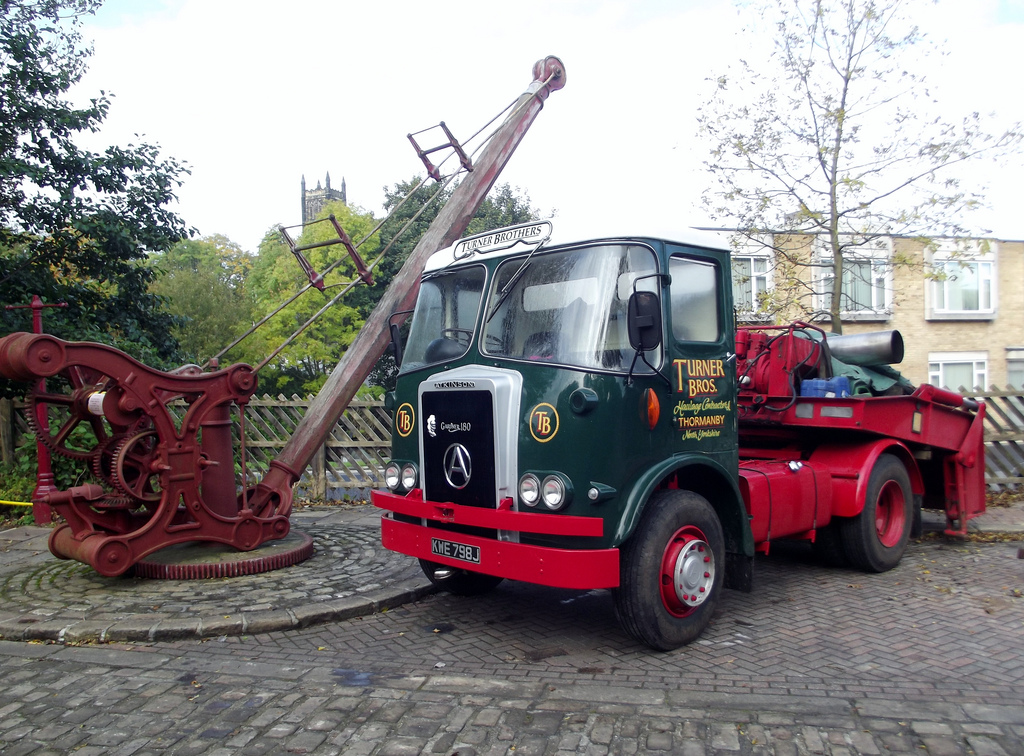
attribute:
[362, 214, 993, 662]
truck — green, red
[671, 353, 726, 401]
print — yellow 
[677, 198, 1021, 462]
building — brown 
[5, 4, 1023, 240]
sky — blue 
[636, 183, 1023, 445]
building — Beige 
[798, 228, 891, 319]
window — white 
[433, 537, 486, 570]
license — Black 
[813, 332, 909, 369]
pipe — Large 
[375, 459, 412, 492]
headlight — white 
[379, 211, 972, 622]
vehicle — Green and red 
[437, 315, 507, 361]
steering wheel — Black 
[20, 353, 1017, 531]
fence — Long , brown 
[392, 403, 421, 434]
circle — yellow 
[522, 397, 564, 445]
circle — yellow 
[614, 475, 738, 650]
tire — black 